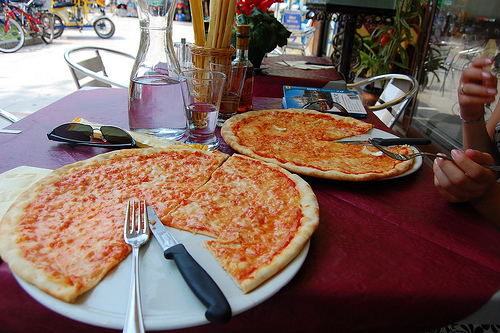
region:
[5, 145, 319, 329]
a pizza with two pieces missing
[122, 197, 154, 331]
a silver fork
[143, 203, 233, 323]
a knife with a black handle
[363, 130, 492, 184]
a hand holding a fork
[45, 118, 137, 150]
a pair of sunglasses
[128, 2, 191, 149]
half filled vase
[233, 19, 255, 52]
a brown bottle cork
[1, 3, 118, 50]
a group of bikes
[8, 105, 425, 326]
two pizzas on a table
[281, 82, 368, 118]
a book sitting on the table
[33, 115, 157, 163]
sunglasses on table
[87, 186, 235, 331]
knife and fork on plate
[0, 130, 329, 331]
pizza on plate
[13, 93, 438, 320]
two pizza's on white plates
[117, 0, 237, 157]
jar of water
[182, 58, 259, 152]
glass of water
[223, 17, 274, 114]
sauce in a bottle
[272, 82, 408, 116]
tour guide book on table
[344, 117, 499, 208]
lady holding fork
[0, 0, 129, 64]
bicycles parked on side of road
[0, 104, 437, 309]
Two pizzas on the table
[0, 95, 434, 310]
A pair of cheese pizzas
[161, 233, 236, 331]
Black handle on a knife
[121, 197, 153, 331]
Silver fork on the plate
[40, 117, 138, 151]
Folded pair of sunglasses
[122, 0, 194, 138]
Carafe of water on the table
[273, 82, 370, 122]
Book beside the pizza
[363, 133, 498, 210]
Hand holding a fork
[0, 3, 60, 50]
Red bicycle parked on the street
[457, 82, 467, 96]
Ring on a hand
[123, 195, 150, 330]
A FORK ON A PIZZA TRAY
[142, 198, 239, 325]
A KNIFE ON A PIZZA TRAY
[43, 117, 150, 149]
SUNGLASSES ON THE TABLE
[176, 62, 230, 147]
GLASS OF WATER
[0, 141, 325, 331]
PIZZA ON A TRAY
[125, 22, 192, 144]
WATER DECANTER NEAR A GLASS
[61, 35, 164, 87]
A METAL CHAIR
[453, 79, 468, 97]
RING ON A WOMAN'S HAND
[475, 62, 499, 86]
WOMAN'S POLISHED FINGERNAIL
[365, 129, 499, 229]
WOMAN'S HAND HOLDING A FORK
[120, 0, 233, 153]
jar of water on table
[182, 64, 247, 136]
glass of water on table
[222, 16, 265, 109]
bottle of sauce on table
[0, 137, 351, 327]
pizza on plate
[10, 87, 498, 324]
two plates of pizza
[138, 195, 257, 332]
knife with black handle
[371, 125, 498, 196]
lady holding fork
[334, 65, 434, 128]
silver chair by table